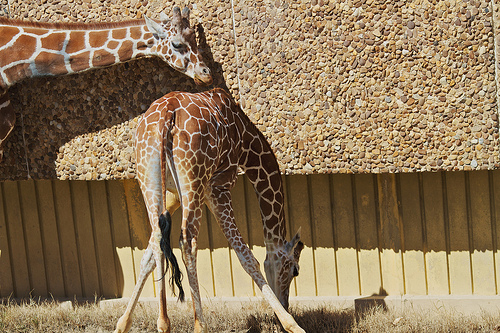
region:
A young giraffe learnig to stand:
[133, 88, 295, 302]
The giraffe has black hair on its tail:
[149, 112, 188, 305]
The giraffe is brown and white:
[156, 106, 264, 203]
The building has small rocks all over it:
[340, 63, 475, 175]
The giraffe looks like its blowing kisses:
[146, 2, 209, 89]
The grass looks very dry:
[1, 297, 71, 331]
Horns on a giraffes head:
[167, 4, 197, 26]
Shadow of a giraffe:
[257, 290, 384, 329]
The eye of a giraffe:
[171, 39, 192, 58]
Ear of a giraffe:
[141, 16, 163, 38]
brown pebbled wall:
[64, 5, 474, 190]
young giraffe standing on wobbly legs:
[101, 85, 319, 332]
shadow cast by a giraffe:
[241, 272, 378, 332]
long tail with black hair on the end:
[149, 105, 191, 299]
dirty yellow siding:
[43, 177, 465, 303]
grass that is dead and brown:
[39, 280, 421, 331]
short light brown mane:
[1, 10, 149, 27]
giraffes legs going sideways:
[106, 182, 308, 331]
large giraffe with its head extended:
[3, 9, 215, 86]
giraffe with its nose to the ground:
[116, 87, 311, 328]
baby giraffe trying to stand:
[111, 78, 315, 331]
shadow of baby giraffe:
[248, 293, 394, 331]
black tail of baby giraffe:
[155, 211, 188, 296]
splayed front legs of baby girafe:
[105, 189, 307, 326]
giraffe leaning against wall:
[0, 16, 212, 86]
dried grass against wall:
[2, 308, 496, 330]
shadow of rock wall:
[7, 180, 481, 297]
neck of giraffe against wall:
[10, 7, 135, 79]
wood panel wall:
[7, 184, 489, 298]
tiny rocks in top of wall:
[8, 5, 493, 170]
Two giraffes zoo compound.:
[19, 18, 319, 324]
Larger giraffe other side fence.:
[2, 6, 219, 85]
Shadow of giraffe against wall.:
[3, 46, 143, 181]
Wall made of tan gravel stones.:
[239, 6, 494, 150]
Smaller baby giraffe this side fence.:
[119, 84, 324, 330]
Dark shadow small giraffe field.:
[227, 281, 406, 331]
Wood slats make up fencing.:
[3, 171, 149, 306]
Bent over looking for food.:
[149, 85, 304, 313]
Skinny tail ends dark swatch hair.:
[159, 99, 189, 308]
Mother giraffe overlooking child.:
[87, 6, 303, 331]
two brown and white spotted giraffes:
[8, 3, 384, 327]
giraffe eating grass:
[104, 77, 322, 317]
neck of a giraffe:
[11, 7, 137, 78]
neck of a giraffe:
[239, 114, 296, 242]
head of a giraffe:
[135, 10, 229, 92]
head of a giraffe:
[263, 210, 315, 307]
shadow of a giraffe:
[271, 284, 399, 331]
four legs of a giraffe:
[97, 205, 297, 331]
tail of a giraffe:
[155, 112, 189, 309]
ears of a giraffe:
[286, 226, 313, 266]